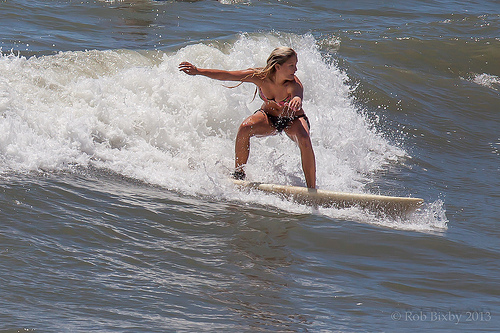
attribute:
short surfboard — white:
[149, 149, 496, 269]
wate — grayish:
[1, 1, 500, 298]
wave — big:
[113, 76, 412, 330]